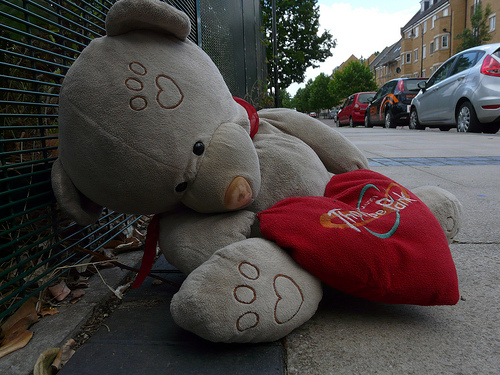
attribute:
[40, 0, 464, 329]
tedy bear — brown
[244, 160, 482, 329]
heart — red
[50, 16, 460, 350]
bear — teddy, large, brown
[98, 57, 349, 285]
bear — Teddy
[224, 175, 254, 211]
nose —  brown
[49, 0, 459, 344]
teddy bear — brown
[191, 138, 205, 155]
eye — black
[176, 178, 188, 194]
eye — black